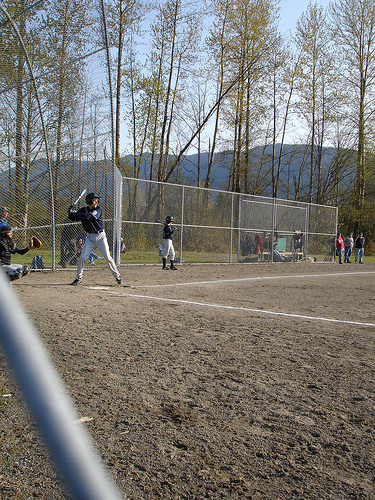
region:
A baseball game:
[4, 17, 365, 460]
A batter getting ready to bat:
[64, 181, 137, 288]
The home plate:
[79, 276, 122, 301]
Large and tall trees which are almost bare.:
[11, 2, 373, 244]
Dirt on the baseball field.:
[135, 323, 283, 455]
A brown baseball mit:
[23, 231, 44, 254]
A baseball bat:
[62, 175, 88, 217]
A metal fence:
[26, 94, 346, 271]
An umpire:
[0, 224, 47, 291]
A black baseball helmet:
[83, 186, 103, 206]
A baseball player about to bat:
[66, 179, 128, 285]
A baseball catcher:
[0, 225, 44, 283]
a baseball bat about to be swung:
[67, 180, 101, 203]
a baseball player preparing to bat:
[155, 203, 190, 279]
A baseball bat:
[154, 218, 185, 232]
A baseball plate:
[84, 279, 107, 294]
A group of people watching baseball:
[326, 222, 373, 267]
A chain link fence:
[37, 130, 340, 254]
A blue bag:
[30, 253, 51, 271]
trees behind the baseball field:
[19, 21, 374, 233]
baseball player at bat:
[55, 181, 142, 295]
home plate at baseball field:
[79, 279, 115, 299]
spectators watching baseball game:
[333, 227, 367, 267]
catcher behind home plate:
[0, 221, 47, 287]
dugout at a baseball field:
[236, 221, 319, 270]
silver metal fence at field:
[183, 182, 236, 265]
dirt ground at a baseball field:
[106, 325, 335, 471]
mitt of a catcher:
[27, 232, 44, 255]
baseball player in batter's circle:
[151, 212, 190, 273]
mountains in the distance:
[13, 139, 374, 180]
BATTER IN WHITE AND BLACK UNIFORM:
[66, 178, 128, 284]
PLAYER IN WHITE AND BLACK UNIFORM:
[154, 209, 190, 267]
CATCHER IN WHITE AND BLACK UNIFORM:
[1, 223, 31, 287]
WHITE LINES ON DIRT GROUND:
[100, 265, 373, 359]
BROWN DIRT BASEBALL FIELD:
[1, 243, 373, 480]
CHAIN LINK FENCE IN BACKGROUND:
[20, 75, 372, 288]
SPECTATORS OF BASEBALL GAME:
[237, 222, 367, 259]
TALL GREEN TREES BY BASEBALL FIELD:
[12, 10, 369, 228]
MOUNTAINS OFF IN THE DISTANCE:
[22, 132, 373, 217]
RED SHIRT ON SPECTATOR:
[334, 228, 355, 253]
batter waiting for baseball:
[65, 169, 130, 286]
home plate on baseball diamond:
[84, 282, 114, 293]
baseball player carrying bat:
[155, 215, 178, 271]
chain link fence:
[112, 163, 338, 267]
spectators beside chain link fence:
[336, 229, 367, 265]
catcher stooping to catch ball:
[1, 223, 46, 280]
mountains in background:
[5, 141, 374, 201]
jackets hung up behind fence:
[241, 233, 303, 257]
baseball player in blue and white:
[65, 191, 127, 286]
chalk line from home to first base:
[111, 288, 374, 330]